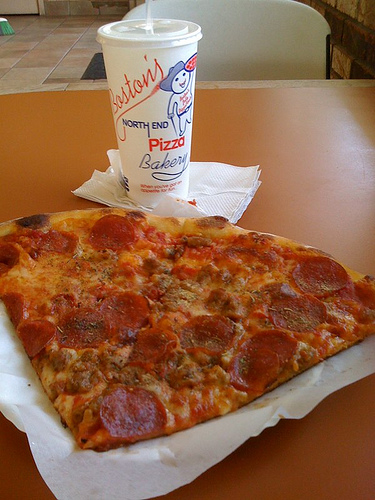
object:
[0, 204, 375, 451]
pizza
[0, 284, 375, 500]
paper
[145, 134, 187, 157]
logo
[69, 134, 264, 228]
napkin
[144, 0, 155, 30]
straw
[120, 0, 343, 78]
chair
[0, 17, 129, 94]
floor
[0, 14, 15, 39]
broom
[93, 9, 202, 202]
cup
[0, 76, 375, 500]
table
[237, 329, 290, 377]
pepperoni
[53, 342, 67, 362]
herbs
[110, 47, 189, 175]
design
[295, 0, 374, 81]
wall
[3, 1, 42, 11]
door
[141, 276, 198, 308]
cheese